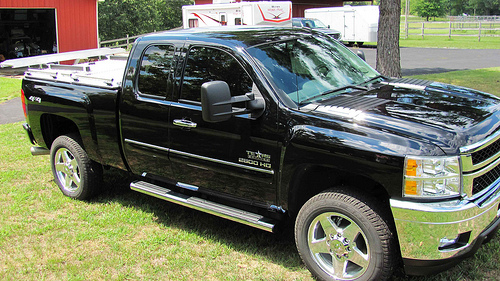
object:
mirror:
[200, 80, 233, 122]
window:
[138, 45, 173, 98]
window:
[246, 35, 379, 104]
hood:
[306, 78, 500, 156]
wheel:
[293, 184, 399, 280]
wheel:
[49, 133, 103, 200]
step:
[129, 180, 271, 229]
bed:
[24, 48, 131, 91]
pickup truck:
[19, 26, 500, 281]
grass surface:
[401, 213, 437, 258]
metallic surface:
[399, 203, 437, 260]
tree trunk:
[374, 15, 399, 71]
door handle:
[173, 120, 198, 128]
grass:
[0, 211, 180, 276]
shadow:
[405, 60, 461, 78]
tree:
[376, 0, 402, 78]